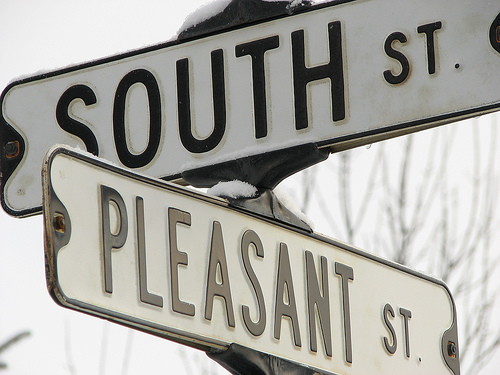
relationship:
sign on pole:
[48, 169, 461, 374] [226, 165, 324, 235]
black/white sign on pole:
[0, 6, 500, 218] [226, 165, 324, 235]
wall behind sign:
[2, 4, 498, 373] [44, 142, 462, 372]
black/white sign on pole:
[13, 6, 492, 370] [173, 5, 338, 365]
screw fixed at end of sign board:
[48, 209, 70, 240] [10, 139, 495, 373]